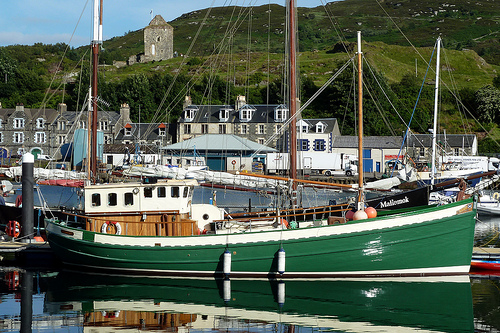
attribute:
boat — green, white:
[45, 189, 485, 331]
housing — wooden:
[78, 208, 206, 237]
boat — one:
[49, 214, 485, 313]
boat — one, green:
[33, 211, 477, 318]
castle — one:
[130, 18, 173, 60]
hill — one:
[100, 34, 268, 98]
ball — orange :
[361, 200, 382, 229]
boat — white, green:
[39, 200, 489, 324]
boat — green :
[45, 202, 478, 309]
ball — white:
[342, 195, 367, 224]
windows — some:
[86, 187, 137, 214]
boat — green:
[35, 180, 485, 320]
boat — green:
[24, 198, 460, 331]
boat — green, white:
[34, 191, 476, 285]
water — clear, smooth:
[51, 274, 384, 331]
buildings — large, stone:
[143, 19, 173, 63]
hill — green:
[180, 19, 281, 79]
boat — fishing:
[35, 173, 485, 292]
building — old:
[7, 110, 472, 155]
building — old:
[181, 101, 291, 153]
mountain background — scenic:
[4, 0, 490, 138]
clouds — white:
[3, 29, 82, 46]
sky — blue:
[3, 0, 189, 50]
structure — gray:
[139, 11, 183, 63]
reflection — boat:
[72, 269, 409, 318]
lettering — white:
[376, 192, 415, 210]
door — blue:
[372, 159, 382, 179]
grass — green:
[200, 23, 271, 93]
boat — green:
[0, 193, 481, 276]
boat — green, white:
[26, 174, 482, 330]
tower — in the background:
[131, 2, 181, 71]